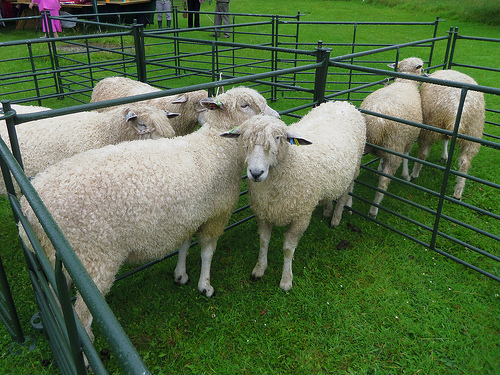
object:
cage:
[41, 5, 302, 101]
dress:
[36, 0, 63, 32]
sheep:
[217, 99, 366, 292]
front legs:
[278, 214, 313, 293]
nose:
[247, 168, 264, 180]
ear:
[284, 135, 313, 146]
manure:
[335, 238, 355, 250]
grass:
[0, 0, 499, 374]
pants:
[184, 2, 202, 29]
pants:
[213, 2, 231, 38]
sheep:
[357, 55, 424, 220]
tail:
[368, 117, 385, 148]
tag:
[294, 139, 298, 145]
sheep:
[409, 69, 485, 202]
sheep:
[16, 86, 283, 349]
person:
[27, 0, 75, 39]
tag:
[288, 141, 295, 146]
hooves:
[251, 265, 267, 280]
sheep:
[89, 75, 214, 138]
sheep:
[0, 102, 182, 205]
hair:
[231, 114, 292, 164]